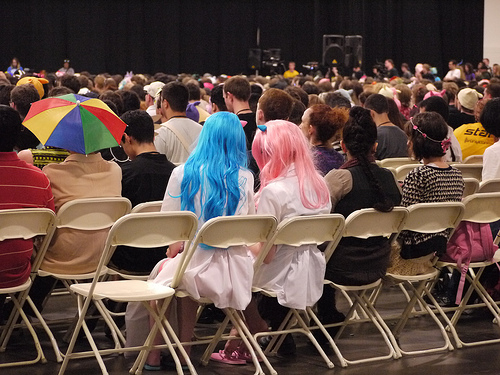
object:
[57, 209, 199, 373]
chair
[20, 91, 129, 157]
umbrella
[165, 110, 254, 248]
wig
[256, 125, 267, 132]
horn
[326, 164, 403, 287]
vest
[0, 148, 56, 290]
shirt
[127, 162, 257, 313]
dress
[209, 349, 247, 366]
sandal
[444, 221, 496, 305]
backpack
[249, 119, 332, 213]
hair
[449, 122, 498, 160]
t-shirt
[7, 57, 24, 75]
lady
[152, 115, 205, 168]
shirt 2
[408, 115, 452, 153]
band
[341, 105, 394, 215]
braided hair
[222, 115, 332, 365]
girl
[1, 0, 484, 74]
curtain